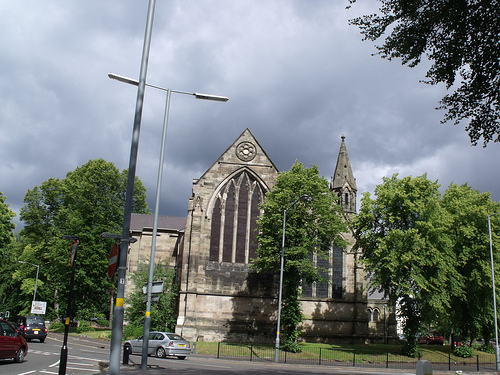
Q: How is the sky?
A: Cloudy.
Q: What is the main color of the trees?
A: Green.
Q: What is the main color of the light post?
A: Gray.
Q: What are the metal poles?
A: Lights.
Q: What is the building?
A: Church.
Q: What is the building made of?
A: Stone.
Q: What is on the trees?
A: Leaves.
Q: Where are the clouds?
A: Sky.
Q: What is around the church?
A: Fence.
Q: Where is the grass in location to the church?
A: Front.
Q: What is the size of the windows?
A: Large.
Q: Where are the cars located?
A: Intersection.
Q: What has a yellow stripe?
A: Poles.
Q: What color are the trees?
A: Green.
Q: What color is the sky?
A: Gray.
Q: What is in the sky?
A: Clouds.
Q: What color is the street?
A: Black.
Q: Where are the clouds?
A: In the sky.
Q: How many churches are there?
A: One.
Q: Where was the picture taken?
A: In front of a church.